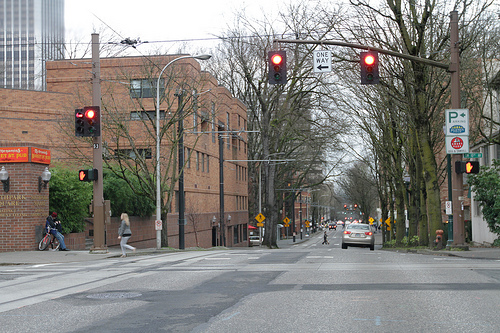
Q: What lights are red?
A: Traffic lights.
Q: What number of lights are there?
A: 5.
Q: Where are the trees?
A: Scattered throughout.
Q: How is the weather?
A: Cloudy.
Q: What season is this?
A: Fall.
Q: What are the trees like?
A: Leafless.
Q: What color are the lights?
A: Red.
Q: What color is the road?
A: Black.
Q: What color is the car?
A: Silver.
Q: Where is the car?
A: On the road.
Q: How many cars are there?
A: 1.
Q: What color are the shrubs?
A: Green.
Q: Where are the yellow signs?
A: Side of road.